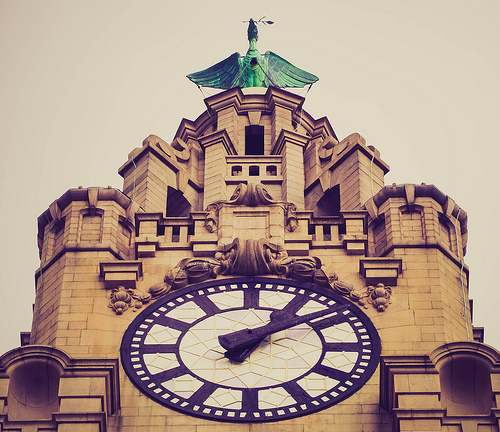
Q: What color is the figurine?
A: Green.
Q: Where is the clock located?
A: On building.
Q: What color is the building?
A: Tan.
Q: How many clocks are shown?
A: One.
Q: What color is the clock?
A: White.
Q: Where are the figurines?
A: On top of building.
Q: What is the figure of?
A: A bird.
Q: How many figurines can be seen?
A: One.